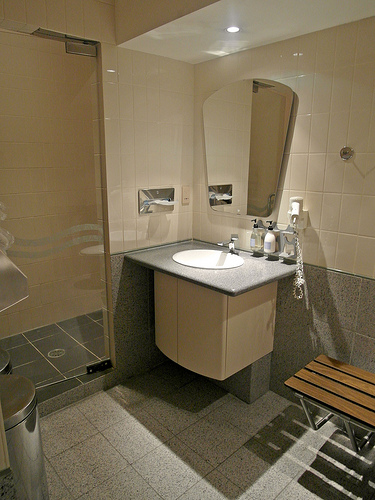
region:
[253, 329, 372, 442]
wooden bench on the wall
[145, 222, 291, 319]
a sink in the bathroom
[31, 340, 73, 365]
shower drain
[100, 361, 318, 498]
sink shadow on the tile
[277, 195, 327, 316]
white hairdryer and cord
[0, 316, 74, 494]
silver steel garbage can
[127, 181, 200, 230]
paper towel dispenser on the wall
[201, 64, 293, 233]
mirror on the bathroom wall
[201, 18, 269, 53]
light above the sink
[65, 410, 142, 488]
white tile on the floor of the bathroom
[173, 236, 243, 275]
A bathroom sink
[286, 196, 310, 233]
A white hair dryer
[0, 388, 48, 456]
A silver trash can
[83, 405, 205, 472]
The tile is grey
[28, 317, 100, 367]
A shower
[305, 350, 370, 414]
A brown bench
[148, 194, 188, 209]
tissues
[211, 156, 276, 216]
A clear mirror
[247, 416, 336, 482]
The shadow from the bench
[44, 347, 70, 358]
A shower drain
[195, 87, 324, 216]
bathroom mirror located above sink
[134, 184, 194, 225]
silver paper towel dispenser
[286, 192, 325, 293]
white wall mounted hair dryer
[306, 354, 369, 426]
brown wooden bench with slates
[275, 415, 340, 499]
shadow of bench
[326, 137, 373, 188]
silver wall mounted towel holder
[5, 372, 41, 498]
silver flip top trash can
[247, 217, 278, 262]
wall mounted soap dispenser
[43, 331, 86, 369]
silver circular shower drain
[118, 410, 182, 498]
grey square patterned floor tile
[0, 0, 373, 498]
a bathroom at a gym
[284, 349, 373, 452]
a bench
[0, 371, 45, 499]
a metal wastebasket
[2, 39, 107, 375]
a glass shower door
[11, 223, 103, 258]
etching on a shower door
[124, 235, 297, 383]
a small sink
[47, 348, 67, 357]
a drain in a shower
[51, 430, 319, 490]
tile flooring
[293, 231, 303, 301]
the cord of an electrical appliance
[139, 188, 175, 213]
a metal tissue dispenser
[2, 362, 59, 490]
a metal shiny trash can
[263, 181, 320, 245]
a white blow dryer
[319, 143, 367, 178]
a mirror on the wall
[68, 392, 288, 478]
grey tiles on the floor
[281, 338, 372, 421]
a brown small bench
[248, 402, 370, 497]
a shadow of the bench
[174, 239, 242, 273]
a round white sink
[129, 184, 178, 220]
a metal tissue dispenser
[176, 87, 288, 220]
a mirror over the sink